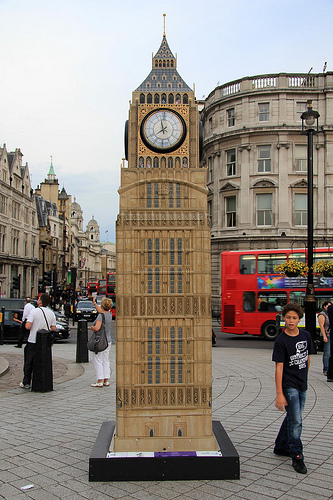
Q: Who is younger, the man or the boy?
A: The boy is younger than the man.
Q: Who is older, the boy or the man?
A: The man is older than the boy.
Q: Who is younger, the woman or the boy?
A: The boy is younger than the woman.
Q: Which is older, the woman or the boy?
A: The woman is older than the boy.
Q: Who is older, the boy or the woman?
A: The woman is older than the boy.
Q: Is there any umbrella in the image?
A: No, there are no umbrellas.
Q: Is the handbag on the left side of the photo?
A: Yes, the handbag is on the left of the image.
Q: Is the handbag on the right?
A: No, the handbag is on the left of the image.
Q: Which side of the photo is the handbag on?
A: The handbag is on the left of the image.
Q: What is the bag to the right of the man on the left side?
A: The bag is a handbag.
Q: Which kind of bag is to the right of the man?
A: The bag is a handbag.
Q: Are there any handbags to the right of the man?
A: Yes, there is a handbag to the right of the man.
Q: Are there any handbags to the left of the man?
A: No, the handbag is to the right of the man.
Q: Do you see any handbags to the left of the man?
A: No, the handbag is to the right of the man.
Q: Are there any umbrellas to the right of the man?
A: No, there is a handbag to the right of the man.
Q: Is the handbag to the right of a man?
A: Yes, the handbag is to the right of a man.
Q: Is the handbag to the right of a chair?
A: No, the handbag is to the right of a man.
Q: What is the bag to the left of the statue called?
A: The bag is a handbag.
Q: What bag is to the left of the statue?
A: The bag is a handbag.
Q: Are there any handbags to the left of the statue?
A: Yes, there is a handbag to the left of the statue.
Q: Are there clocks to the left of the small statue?
A: No, there is a handbag to the left of the statue.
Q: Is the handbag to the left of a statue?
A: Yes, the handbag is to the left of a statue.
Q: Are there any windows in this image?
A: Yes, there is a window.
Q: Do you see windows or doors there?
A: Yes, there is a window.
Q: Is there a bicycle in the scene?
A: No, there are no bicycles.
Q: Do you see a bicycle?
A: No, there are no bicycles.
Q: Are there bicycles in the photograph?
A: No, there are no bicycles.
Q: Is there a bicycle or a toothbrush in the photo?
A: No, there are no bicycles or toothbrushes.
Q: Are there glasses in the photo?
A: No, there are no glasses.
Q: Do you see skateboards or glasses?
A: No, there are no glasses or skateboards.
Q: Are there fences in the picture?
A: No, there are no fences.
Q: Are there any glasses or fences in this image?
A: No, there are no fences or glasses.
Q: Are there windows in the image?
A: Yes, there is a window.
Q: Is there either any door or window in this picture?
A: Yes, there is a window.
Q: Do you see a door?
A: No, there are no doors.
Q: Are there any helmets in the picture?
A: No, there are no helmets.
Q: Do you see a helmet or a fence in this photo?
A: No, there are no helmets or fences.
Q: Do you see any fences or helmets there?
A: No, there are no helmets or fences.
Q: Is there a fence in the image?
A: No, there are no fences.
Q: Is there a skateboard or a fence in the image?
A: No, there are no fences or skateboards.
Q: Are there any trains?
A: No, there are no trains.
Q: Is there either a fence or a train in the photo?
A: No, there are no trains or fences.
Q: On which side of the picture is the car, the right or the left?
A: The car is on the left of the image.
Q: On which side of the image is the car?
A: The car is on the left of the image.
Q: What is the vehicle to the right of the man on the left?
A: The vehicle is a car.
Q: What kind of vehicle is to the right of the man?
A: The vehicle is a car.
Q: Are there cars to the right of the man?
A: Yes, there is a car to the right of the man.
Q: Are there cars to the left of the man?
A: No, the car is to the right of the man.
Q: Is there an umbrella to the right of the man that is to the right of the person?
A: No, there is a car to the right of the man.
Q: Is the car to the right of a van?
A: No, the car is to the right of the man.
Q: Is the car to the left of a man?
A: No, the car is to the right of a man.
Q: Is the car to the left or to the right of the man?
A: The car is to the right of the man.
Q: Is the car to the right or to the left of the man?
A: The car is to the right of the man.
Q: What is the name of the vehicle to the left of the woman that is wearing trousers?
A: The vehicle is a car.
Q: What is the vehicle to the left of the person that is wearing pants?
A: The vehicle is a car.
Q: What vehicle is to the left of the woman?
A: The vehicle is a car.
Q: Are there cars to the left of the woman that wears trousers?
A: Yes, there is a car to the left of the woman.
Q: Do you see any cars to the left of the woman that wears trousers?
A: Yes, there is a car to the left of the woman.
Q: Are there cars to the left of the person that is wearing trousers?
A: Yes, there is a car to the left of the woman.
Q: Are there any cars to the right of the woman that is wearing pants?
A: No, the car is to the left of the woman.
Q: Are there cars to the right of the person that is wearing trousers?
A: No, the car is to the left of the woman.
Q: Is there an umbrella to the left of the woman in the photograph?
A: No, there is a car to the left of the woman.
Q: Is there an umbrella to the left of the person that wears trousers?
A: No, there is a car to the left of the woman.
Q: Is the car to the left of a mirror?
A: No, the car is to the left of a woman.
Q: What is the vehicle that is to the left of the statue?
A: The vehicle is a car.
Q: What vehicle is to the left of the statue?
A: The vehicle is a car.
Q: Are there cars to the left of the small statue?
A: Yes, there is a car to the left of the statue.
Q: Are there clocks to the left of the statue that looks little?
A: No, there is a car to the left of the statue.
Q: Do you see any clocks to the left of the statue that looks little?
A: No, there is a car to the left of the statue.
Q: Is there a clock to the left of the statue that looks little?
A: No, there is a car to the left of the statue.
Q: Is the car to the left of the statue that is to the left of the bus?
A: Yes, the car is to the left of the statue.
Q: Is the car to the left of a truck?
A: No, the car is to the left of the statue.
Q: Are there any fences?
A: No, there are no fences.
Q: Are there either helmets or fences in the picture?
A: No, there are no fences or helmets.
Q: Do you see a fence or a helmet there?
A: No, there are no fences or helmets.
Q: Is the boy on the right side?
A: Yes, the boy is on the right of the image.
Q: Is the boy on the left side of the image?
A: No, the boy is on the right of the image.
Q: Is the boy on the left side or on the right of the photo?
A: The boy is on the right of the image.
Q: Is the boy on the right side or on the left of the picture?
A: The boy is on the right of the image.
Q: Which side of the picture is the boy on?
A: The boy is on the right of the image.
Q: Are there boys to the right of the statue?
A: Yes, there is a boy to the right of the statue.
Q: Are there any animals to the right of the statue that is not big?
A: No, there is a boy to the right of the statue.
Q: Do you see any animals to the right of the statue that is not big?
A: No, there is a boy to the right of the statue.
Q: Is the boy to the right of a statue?
A: Yes, the boy is to the right of a statue.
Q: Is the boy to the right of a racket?
A: No, the boy is to the right of a statue.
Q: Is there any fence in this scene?
A: No, there are no fences.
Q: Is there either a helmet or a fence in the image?
A: No, there are no fences or helmets.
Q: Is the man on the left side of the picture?
A: Yes, the man is on the left of the image.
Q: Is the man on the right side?
A: No, the man is on the left of the image.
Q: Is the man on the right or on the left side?
A: The man is on the left of the image.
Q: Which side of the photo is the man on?
A: The man is on the left of the image.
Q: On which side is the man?
A: The man is on the left of the image.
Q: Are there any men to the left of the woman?
A: Yes, there is a man to the left of the woman.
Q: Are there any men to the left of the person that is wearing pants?
A: Yes, there is a man to the left of the woman.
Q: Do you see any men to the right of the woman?
A: No, the man is to the left of the woman.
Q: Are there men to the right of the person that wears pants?
A: No, the man is to the left of the woman.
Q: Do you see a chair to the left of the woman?
A: No, there is a man to the left of the woman.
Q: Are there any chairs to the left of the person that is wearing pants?
A: No, there is a man to the left of the woman.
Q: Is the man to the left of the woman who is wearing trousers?
A: Yes, the man is to the left of the woman.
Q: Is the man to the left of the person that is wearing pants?
A: Yes, the man is to the left of the woman.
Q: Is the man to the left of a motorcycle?
A: No, the man is to the left of the woman.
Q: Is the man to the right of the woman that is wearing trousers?
A: No, the man is to the left of the woman.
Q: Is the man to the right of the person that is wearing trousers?
A: No, the man is to the left of the woman.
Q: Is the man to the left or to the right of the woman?
A: The man is to the left of the woman.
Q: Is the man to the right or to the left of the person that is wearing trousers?
A: The man is to the left of the woman.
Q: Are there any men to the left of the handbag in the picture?
A: Yes, there is a man to the left of the handbag.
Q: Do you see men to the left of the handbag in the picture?
A: Yes, there is a man to the left of the handbag.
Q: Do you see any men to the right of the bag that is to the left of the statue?
A: No, the man is to the left of the handbag.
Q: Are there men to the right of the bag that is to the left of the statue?
A: No, the man is to the left of the handbag.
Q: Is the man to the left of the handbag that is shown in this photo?
A: Yes, the man is to the left of the handbag.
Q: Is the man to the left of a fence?
A: No, the man is to the left of the handbag.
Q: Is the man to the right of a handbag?
A: No, the man is to the left of a handbag.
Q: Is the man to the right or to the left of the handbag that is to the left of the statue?
A: The man is to the left of the handbag.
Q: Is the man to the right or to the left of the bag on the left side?
A: The man is to the left of the handbag.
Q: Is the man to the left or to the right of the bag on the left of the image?
A: The man is to the left of the handbag.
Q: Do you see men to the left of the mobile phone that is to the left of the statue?
A: Yes, there is a man to the left of the mobile phone.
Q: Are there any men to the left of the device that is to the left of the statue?
A: Yes, there is a man to the left of the mobile phone.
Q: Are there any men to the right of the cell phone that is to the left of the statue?
A: No, the man is to the left of the cell phone.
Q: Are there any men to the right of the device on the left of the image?
A: No, the man is to the left of the cell phone.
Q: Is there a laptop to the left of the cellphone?
A: No, there is a man to the left of the cellphone.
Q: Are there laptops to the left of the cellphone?
A: No, there is a man to the left of the cellphone.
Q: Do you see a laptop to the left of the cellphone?
A: No, there is a man to the left of the cellphone.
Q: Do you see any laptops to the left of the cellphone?
A: No, there is a man to the left of the cellphone.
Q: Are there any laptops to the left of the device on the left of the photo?
A: No, there is a man to the left of the cellphone.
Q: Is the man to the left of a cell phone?
A: Yes, the man is to the left of a cell phone.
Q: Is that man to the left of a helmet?
A: No, the man is to the left of a cell phone.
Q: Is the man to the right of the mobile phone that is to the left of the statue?
A: No, the man is to the left of the cell phone.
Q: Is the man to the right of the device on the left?
A: No, the man is to the left of the cell phone.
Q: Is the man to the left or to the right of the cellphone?
A: The man is to the left of the cellphone.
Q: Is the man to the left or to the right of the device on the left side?
A: The man is to the left of the cellphone.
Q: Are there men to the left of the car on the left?
A: Yes, there is a man to the left of the car.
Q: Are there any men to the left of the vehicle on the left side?
A: Yes, there is a man to the left of the car.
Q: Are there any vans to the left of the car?
A: No, there is a man to the left of the car.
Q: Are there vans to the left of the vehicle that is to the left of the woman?
A: No, there is a man to the left of the car.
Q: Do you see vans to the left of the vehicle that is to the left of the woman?
A: No, there is a man to the left of the car.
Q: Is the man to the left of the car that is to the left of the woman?
A: Yes, the man is to the left of the car.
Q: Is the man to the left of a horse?
A: No, the man is to the left of the car.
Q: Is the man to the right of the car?
A: No, the man is to the left of the car.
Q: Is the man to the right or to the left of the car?
A: The man is to the left of the car.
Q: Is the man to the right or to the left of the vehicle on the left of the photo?
A: The man is to the left of the car.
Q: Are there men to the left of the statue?
A: Yes, there is a man to the left of the statue.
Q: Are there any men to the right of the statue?
A: No, the man is to the left of the statue.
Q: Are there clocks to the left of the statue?
A: No, there is a man to the left of the statue.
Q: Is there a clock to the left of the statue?
A: No, there is a man to the left of the statue.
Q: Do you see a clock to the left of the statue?
A: No, there is a man to the left of the statue.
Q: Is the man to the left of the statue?
A: Yes, the man is to the left of the statue.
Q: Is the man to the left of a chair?
A: No, the man is to the left of the statue.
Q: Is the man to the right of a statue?
A: No, the man is to the left of a statue.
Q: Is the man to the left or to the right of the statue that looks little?
A: The man is to the left of the statue.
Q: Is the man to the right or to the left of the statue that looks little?
A: The man is to the left of the statue.